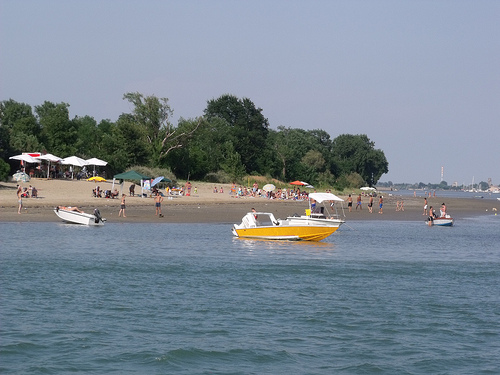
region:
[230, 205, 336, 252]
Motor boat with yellow hull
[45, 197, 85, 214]
Woman laying on white boat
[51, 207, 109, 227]
White motor boat with black outboard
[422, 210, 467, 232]
Red, white, and blue motor boat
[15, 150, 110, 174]
Cluster of beach umbrellas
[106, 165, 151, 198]
Green portable canopy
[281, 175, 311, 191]
a red beach umbrella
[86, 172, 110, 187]
a yellow beach umbrella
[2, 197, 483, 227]
Area of wet sand near the water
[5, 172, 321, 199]
Dry sand away from the water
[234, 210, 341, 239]
a yellow and white boat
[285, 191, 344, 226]
white boat with a sunshade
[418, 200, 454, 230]
a small boat with two passengers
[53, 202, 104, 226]
a boat on the shore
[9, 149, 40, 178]
an umbrellas on the beach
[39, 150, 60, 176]
an umbrella on the beach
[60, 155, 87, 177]
an umbrella on the beach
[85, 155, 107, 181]
an umbrella on the beach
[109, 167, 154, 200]
a shade with four posts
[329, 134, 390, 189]
trees near the water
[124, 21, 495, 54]
clear blue sky above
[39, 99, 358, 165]
green different shades of trees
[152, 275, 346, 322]
blue and green calm water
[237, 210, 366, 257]
yellow and white small boat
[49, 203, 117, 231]
white and blue small boat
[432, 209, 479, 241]
red and white small boat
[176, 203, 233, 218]
wet sand on shore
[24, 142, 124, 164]
row of white umbrellas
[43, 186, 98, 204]
untouched tan sand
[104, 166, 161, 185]
green beach umbrella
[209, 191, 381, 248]
yellow and white boat in water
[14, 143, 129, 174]
row of four white umbrellas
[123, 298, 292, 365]
small waves in the water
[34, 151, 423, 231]
people enjoying themselves on beach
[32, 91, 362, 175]
tall green leafy trees along beach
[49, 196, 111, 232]
white motorboat on water's edge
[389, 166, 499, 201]
boats and water in the distance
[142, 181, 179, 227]
person in blue swim trunks on beach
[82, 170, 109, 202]
yellow beach umbrella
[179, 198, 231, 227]
brown wet sandy beach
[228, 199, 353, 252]
a yellow and white boat floating in the water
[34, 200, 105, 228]
a white boat on the beach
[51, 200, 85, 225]
a person laying on a boat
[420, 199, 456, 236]
two people in a boat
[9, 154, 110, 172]
several white umbrellas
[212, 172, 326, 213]
several people on a beach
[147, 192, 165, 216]
a person standing on a beach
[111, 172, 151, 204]
a green canopy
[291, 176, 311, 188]
a orange and white umbrella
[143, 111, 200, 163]
a tree with bare branches